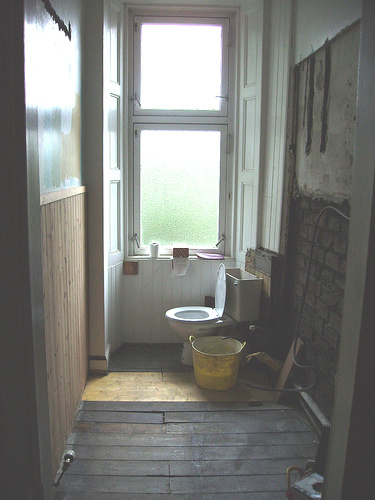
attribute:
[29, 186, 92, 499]
wood — wooden, timber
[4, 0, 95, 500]
wall — white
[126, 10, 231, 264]
window — letting sun in, large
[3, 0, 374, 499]
bathroom — being remodeled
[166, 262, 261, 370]
toilet — white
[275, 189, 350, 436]
brick area — old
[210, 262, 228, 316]
lid — up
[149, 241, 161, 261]
toilet paper — rolled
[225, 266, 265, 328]
toilet tank — uncovered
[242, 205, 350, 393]
cord — hanging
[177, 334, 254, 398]
bucket — yellow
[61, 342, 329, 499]
floor — wooden, brown